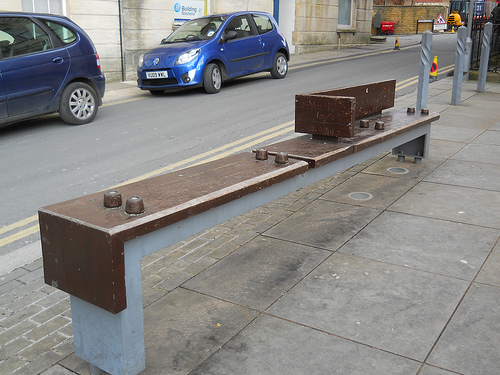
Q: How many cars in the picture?
A: Two.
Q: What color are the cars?
A: Blue.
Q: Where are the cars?
A: The street.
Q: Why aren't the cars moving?
A: They're parked.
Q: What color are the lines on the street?
A: Yellow.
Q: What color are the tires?
A: Black.